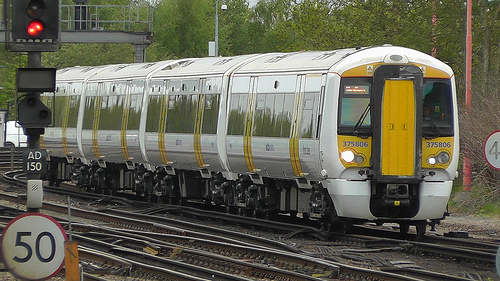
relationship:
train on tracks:
[39, 48, 460, 234] [67, 195, 293, 276]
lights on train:
[338, 145, 457, 167] [31, 38, 462, 242]